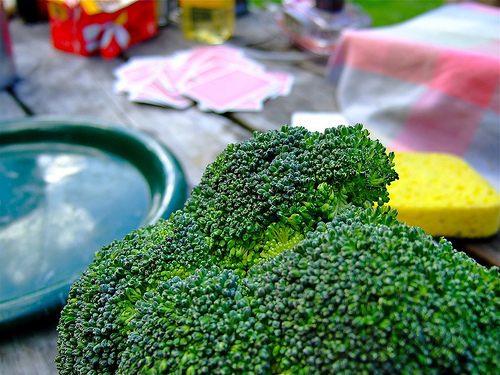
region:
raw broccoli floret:
[37, 129, 495, 374]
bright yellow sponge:
[350, 138, 492, 246]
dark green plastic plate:
[9, 85, 200, 345]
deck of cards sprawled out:
[114, 33, 291, 113]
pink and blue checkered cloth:
[324, 4, 499, 184]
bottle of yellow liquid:
[179, 0, 234, 49]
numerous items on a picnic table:
[3, 0, 491, 358]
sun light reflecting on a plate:
[23, 145, 106, 231]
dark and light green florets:
[218, 188, 373, 303]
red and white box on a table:
[51, 0, 155, 75]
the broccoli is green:
[153, 223, 227, 315]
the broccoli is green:
[250, 118, 379, 263]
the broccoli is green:
[344, 193, 441, 362]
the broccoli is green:
[116, 206, 275, 368]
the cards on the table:
[141, 43, 278, 130]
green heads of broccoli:
[59, 128, 494, 356]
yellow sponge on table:
[355, 146, 498, 228]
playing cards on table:
[98, 35, 282, 135]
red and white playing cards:
[113, 28, 265, 118]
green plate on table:
[2, 108, 169, 310]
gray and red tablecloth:
[328, 7, 498, 160]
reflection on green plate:
[16, 142, 93, 274]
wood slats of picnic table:
[5, 20, 442, 332]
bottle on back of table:
[178, 3, 230, 44]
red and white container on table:
[40, 7, 183, 61]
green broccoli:
[77, 138, 472, 358]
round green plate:
[7, 95, 180, 337]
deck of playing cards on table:
[100, 42, 292, 117]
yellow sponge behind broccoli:
[345, 155, 496, 223]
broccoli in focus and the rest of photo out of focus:
[28, 7, 478, 357]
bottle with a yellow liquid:
[175, 2, 245, 42]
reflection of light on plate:
[30, 126, 96, 273]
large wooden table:
[20, 25, 350, 121]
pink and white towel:
[325, 17, 485, 122]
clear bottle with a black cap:
[285, 0, 360, 54]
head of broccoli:
[34, 106, 498, 372]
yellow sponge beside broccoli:
[328, 137, 495, 235]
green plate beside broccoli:
[3, 111, 194, 337]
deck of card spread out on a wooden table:
[110, 37, 295, 118]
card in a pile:
[177, 63, 272, 113]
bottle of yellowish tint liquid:
[178, 2, 241, 40]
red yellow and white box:
[42, 1, 161, 61]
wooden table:
[3, 9, 497, 370]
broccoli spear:
[196, 114, 402, 253]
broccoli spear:
[262, 219, 498, 367]